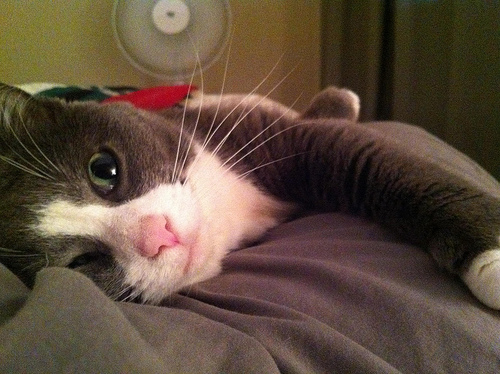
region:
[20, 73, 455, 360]
Cat laying on the blanket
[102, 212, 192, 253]
Cat has a pink nose.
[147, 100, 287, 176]
Cat has long whiskers.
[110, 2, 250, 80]
A portable fan behind the cat.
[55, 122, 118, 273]
The cat has green eyes.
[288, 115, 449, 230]
The cat has a gray leg.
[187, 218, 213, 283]
Cat mouth is closed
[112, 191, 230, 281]
Cat face is white.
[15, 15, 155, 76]
The wall is yellow.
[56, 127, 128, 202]
The cat's eye is open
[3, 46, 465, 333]
cat laying on the bed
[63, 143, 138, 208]
cat with green eyes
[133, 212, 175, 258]
cat with a pink nose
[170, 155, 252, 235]
cat with white chest hair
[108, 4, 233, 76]
Fan blowing on a cat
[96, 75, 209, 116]
red pillow on the bed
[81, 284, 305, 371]
cat laying on a gray blanket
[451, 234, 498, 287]
cat with a white paw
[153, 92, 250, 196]
cat with white whiskers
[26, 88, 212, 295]
cat head on the bed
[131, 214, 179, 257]
Pink nose on a cat's face.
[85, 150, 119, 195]
A cat's left green and black eye.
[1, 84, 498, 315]
A dark grey and white cat.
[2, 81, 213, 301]
A dark grey and white cat with a pink nose.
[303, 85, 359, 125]
A grey and white right paw of a cat.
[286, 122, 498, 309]
A long grey and white left arm of a cat.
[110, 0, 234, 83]
A round white fan that is on.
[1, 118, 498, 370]
A grey blanket under a cat.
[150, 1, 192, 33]
The smaller white solid circle on a moving fan.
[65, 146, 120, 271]
Green eyes of a cat.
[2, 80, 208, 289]
cat's gray and white face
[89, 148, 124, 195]
cat's green eye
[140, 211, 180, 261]
cat's pink nose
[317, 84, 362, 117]
cat's back paw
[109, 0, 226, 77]
fan in the background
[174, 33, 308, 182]
cat's white whiskers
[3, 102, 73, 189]
whiskers above the cat's eye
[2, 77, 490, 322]
gray and white cat looking at the camera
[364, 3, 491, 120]
green curtain in the background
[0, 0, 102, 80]
beige wall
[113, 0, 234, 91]
White fan leaning against fan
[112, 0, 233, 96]
White fan behind cat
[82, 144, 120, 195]
Eye of cat is green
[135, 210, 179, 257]
Small nose is pink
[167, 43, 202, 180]
White whisker on cat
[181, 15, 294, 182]
White whisker on cat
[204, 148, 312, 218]
White whisker on cat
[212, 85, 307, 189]
White whisker on cat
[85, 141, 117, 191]
Eye of cat is opened